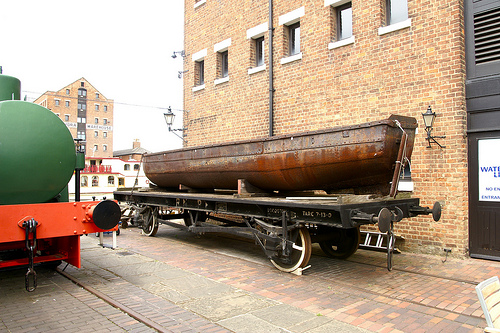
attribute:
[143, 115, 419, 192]
boat — rusty, large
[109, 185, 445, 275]
carrier — rusted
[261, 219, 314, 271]
front wheel — white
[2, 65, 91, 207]
tank — green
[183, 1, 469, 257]
building — tall, brick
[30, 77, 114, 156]
building — large, tall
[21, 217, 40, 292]
chain — black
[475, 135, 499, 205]
sign — white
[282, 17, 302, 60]
window — small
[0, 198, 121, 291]
trailer — orange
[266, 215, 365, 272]
wheels — pair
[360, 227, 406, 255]
ladder — silver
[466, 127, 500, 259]
door — brown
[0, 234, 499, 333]
road — brick